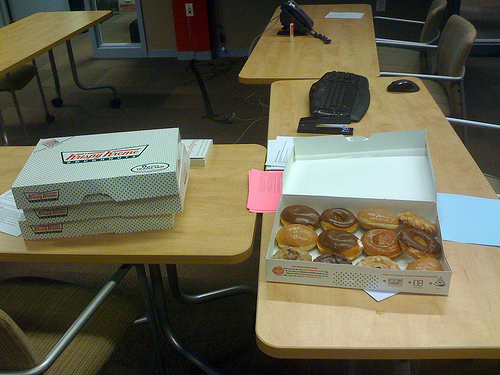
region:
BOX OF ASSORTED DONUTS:
[262, 191, 468, 296]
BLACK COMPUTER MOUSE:
[384, 75, 421, 99]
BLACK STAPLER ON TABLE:
[294, 112, 364, 136]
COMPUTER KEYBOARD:
[288, 67, 388, 122]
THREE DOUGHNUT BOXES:
[11, 122, 194, 248]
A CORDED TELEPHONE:
[267, 0, 339, 47]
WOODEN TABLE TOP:
[232, 1, 399, 86]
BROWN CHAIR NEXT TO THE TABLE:
[373, 11, 475, 122]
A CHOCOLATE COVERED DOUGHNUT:
[318, 200, 357, 234]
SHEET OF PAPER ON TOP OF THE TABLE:
[319, 5, 371, 27]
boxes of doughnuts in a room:
[57, 12, 479, 342]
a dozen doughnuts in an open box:
[255, 120, 450, 305]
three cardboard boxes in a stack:
[15, 120, 210, 245]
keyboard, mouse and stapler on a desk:
[260, 61, 450, 131]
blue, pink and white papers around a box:
[245, 120, 485, 320]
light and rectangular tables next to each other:
[22, 11, 477, 356]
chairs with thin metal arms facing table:
[355, 6, 485, 171]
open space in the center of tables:
[10, 20, 285, 165]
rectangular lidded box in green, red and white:
[6, 131, 191, 193]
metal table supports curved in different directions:
[75, 240, 252, 362]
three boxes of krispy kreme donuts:
[12, 112, 212, 244]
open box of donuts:
[264, 126, 495, 288]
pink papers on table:
[237, 165, 304, 222]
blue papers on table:
[431, 183, 498, 245]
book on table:
[180, 137, 241, 167]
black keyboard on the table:
[305, 59, 385, 126]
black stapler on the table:
[286, 106, 371, 151]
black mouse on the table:
[380, 78, 430, 102]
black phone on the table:
[272, 0, 339, 54]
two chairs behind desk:
[374, 0, 469, 97]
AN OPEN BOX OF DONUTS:
[269, 126, 453, 298]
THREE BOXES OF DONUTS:
[11, 131, 190, 234]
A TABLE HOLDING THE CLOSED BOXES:
[5, 142, 257, 264]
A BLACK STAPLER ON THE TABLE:
[290, 115, 367, 135]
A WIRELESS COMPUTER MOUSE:
[375, 73, 430, 98]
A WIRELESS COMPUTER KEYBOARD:
[312, 57, 365, 118]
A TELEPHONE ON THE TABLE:
[270, 3, 338, 44]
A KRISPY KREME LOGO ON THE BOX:
[57, 143, 147, 160]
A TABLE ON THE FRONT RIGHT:
[260, 72, 495, 353]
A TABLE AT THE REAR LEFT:
[1, 5, 126, 120]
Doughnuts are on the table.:
[274, 162, 497, 308]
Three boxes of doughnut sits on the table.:
[8, 145, 215, 253]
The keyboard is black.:
[294, 59, 369, 126]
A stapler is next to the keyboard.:
[296, 107, 363, 136]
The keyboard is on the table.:
[305, 63, 375, 134]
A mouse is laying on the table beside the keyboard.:
[378, 71, 428, 108]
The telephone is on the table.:
[275, 2, 335, 48]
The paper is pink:
[231, 168, 282, 223]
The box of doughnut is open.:
[271, 140, 451, 304]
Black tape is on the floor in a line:
[181, 51, 232, 131]